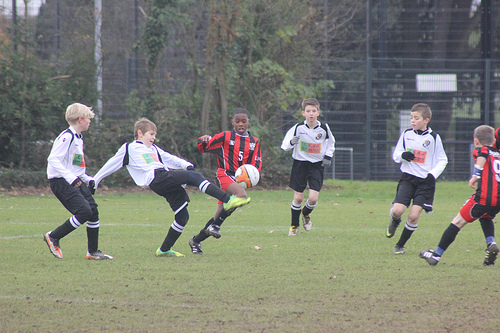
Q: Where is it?
A: This is at the field.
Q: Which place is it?
A: It is a field.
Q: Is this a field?
A: Yes, it is a field.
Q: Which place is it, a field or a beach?
A: It is a field.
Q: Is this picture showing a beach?
A: No, the picture is showing a field.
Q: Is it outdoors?
A: Yes, it is outdoors.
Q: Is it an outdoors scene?
A: Yes, it is outdoors.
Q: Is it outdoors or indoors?
A: It is outdoors.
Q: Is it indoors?
A: No, it is outdoors.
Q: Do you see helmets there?
A: No, there are no helmets.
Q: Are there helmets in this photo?
A: No, there are no helmets.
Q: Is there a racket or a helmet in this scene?
A: No, there are no helmets or rackets.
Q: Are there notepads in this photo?
A: No, there are no notepads.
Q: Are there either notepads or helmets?
A: No, there are no notepads or helmets.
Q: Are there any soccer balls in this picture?
A: Yes, there is a soccer ball.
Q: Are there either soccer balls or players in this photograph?
A: Yes, there is a soccer ball.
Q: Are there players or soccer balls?
A: Yes, there is a soccer ball.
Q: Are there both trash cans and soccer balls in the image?
A: No, there is a soccer ball but no trash cans.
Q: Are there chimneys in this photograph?
A: No, there are no chimneys.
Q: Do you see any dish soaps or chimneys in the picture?
A: No, there are no chimneys or dish soaps.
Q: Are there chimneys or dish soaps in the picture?
A: No, there are no chimneys or dish soaps.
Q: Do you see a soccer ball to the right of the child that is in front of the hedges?
A: Yes, there is a soccer ball to the right of the kid.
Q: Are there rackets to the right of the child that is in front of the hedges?
A: No, there is a soccer ball to the right of the kid.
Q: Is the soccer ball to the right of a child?
A: Yes, the soccer ball is to the right of a child.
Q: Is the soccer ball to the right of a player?
A: No, the soccer ball is to the right of a child.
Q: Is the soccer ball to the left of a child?
A: Yes, the soccer ball is to the left of a child.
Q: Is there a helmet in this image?
A: No, there are no helmets.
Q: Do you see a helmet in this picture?
A: No, there are no helmets.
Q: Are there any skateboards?
A: No, there are no skateboards.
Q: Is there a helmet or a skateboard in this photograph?
A: No, there are no skateboards or helmets.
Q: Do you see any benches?
A: No, there are no benches.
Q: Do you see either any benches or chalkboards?
A: No, there are no benches or chalkboards.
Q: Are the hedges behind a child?
A: Yes, the hedges are behind a child.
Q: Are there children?
A: Yes, there is a child.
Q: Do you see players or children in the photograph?
A: Yes, there is a child.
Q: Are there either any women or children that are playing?
A: Yes, the child is playing.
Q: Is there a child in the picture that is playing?
A: Yes, there is a child that is playing.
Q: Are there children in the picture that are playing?
A: Yes, there is a child that is playing.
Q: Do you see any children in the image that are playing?
A: Yes, there is a child that is playing.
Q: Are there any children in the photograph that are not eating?
A: Yes, there is a child that is playing.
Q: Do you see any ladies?
A: No, there are no ladies.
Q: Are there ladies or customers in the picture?
A: No, there are no ladies or customers.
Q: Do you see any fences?
A: Yes, there is a fence.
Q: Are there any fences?
A: Yes, there is a fence.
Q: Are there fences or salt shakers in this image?
A: Yes, there is a fence.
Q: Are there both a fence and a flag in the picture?
A: No, there is a fence but no flags.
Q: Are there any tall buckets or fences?
A: Yes, there is a tall fence.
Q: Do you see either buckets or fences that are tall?
A: Yes, the fence is tall.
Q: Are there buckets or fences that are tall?
A: Yes, the fence is tall.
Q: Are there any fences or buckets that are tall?
A: Yes, the fence is tall.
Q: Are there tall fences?
A: Yes, there is a tall fence.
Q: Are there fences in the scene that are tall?
A: Yes, there is a fence that is tall.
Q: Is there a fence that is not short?
A: Yes, there is a tall fence.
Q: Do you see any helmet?
A: No, there are no helmets.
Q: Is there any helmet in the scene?
A: No, there are no helmets.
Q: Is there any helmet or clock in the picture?
A: No, there are no helmets or clocks.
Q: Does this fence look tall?
A: Yes, the fence is tall.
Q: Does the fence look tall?
A: Yes, the fence is tall.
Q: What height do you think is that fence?
A: The fence is tall.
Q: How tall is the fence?
A: The fence is tall.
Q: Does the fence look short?
A: No, the fence is tall.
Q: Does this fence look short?
A: No, the fence is tall.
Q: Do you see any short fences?
A: No, there is a fence but it is tall.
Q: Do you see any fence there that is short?
A: No, there is a fence but it is tall.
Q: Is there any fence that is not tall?
A: No, there is a fence but it is tall.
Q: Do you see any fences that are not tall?
A: No, there is a fence but it is tall.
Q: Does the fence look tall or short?
A: The fence is tall.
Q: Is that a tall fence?
A: Yes, that is a tall fence.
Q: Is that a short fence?
A: No, that is a tall fence.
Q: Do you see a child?
A: Yes, there is a child.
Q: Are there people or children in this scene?
A: Yes, there is a child.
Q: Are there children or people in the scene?
A: Yes, there is a child.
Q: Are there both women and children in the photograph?
A: No, there is a child but no women.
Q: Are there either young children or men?
A: Yes, there is a young child.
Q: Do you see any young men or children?
A: Yes, there is a young child.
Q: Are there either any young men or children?
A: Yes, there is a young child.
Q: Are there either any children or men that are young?
A: Yes, the child is young.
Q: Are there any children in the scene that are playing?
A: Yes, there is a child that is playing.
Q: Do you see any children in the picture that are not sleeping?
A: Yes, there is a child that is playing .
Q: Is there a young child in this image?
A: Yes, there is a young child.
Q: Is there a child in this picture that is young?
A: Yes, there is a child that is young.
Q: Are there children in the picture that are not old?
A: Yes, there is an young child.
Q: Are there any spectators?
A: No, there are no spectators.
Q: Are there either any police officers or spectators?
A: No, there are no spectators or police officers.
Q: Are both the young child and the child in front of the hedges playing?
A: Yes, both the child and the kid are playing.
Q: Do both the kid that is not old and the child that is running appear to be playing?
A: Yes, both the kid and the kid are playing.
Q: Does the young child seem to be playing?
A: Yes, the child is playing.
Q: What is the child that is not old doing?
A: The kid is playing.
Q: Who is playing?
A: The child is playing.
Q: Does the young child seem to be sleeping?
A: No, the child is playing.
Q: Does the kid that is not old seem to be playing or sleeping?
A: The child is playing.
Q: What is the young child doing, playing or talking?
A: The kid is playing.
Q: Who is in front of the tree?
A: The kid is in front of the tree.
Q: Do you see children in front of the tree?
A: Yes, there is a child in front of the tree.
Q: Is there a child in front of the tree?
A: Yes, there is a child in front of the tree.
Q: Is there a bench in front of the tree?
A: No, there is a child in front of the tree.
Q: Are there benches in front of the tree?
A: No, there is a child in front of the tree.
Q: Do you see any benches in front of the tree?
A: No, there is a child in front of the tree.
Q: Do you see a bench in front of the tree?
A: No, there is a child in front of the tree.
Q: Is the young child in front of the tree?
A: Yes, the child is in front of the tree.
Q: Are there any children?
A: Yes, there is a child.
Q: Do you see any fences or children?
A: Yes, there is a child.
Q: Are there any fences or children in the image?
A: Yes, there is a child.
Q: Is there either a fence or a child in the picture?
A: Yes, there is a child.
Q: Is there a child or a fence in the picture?
A: Yes, there is a child.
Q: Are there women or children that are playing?
A: Yes, the child is playing.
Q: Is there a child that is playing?
A: Yes, there is a child that is playing.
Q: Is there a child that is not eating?
A: Yes, there is a child that is playing.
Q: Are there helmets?
A: No, there are no helmets.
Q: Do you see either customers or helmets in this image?
A: No, there are no helmets or customers.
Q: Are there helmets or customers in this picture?
A: No, there are no helmets or customers.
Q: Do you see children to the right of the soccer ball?
A: Yes, there is a child to the right of the soccer ball.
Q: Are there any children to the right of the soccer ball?
A: Yes, there is a child to the right of the soccer ball.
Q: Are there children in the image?
A: Yes, there is a child.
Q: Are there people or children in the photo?
A: Yes, there is a child.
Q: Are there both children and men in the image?
A: No, there is a child but no men.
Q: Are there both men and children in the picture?
A: No, there is a child but no men.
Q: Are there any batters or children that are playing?
A: Yes, the child is playing.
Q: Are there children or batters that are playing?
A: Yes, the child is playing.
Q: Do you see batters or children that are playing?
A: Yes, the child is playing.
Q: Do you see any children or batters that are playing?
A: Yes, the child is playing.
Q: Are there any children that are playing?
A: Yes, there is a child that is playing.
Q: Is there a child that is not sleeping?
A: Yes, there is a child that is playing.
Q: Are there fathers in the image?
A: No, there are no fathers.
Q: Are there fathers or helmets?
A: No, there are no fathers or helmets.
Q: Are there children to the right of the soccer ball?
A: Yes, there is a child to the right of the soccer ball.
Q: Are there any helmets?
A: No, there are no helmets.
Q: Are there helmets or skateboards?
A: No, there are no helmets or skateboards.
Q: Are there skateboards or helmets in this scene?
A: No, there are no helmets or skateboards.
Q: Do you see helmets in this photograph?
A: No, there are no helmets.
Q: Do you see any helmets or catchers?
A: No, there are no helmets or catchers.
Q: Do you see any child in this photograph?
A: Yes, there is a child.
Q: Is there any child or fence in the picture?
A: Yes, there is a child.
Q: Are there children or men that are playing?
A: Yes, the child is playing.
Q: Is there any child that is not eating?
A: Yes, there is a child that is playing.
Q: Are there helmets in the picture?
A: No, there are no helmets.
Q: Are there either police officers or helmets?
A: No, there are no helmets or police officers.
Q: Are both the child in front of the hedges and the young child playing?
A: Yes, both the child and the child are playing.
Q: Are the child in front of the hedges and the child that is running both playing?
A: Yes, both the kid and the child are playing.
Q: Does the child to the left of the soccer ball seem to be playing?
A: Yes, the kid is playing.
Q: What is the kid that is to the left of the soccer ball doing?
A: The child is playing.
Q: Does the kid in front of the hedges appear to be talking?
A: No, the child is playing.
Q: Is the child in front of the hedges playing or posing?
A: The child is playing.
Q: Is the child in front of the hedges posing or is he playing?
A: The child is playing.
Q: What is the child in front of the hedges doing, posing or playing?
A: The child is playing.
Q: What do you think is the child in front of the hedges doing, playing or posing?
A: The child is playing.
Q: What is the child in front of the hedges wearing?
A: The kid is wearing a uniform.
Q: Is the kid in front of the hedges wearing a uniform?
A: Yes, the child is wearing a uniform.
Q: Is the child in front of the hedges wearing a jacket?
A: No, the child is wearing a uniform.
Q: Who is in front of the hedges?
A: The child is in front of the hedges.